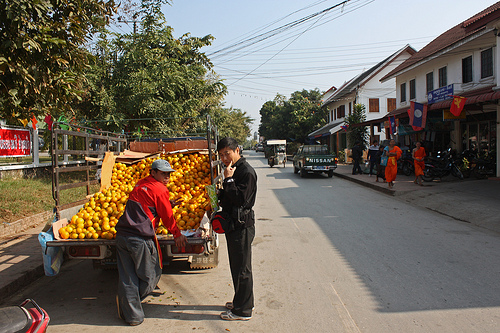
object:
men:
[212, 137, 256, 323]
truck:
[41, 115, 224, 271]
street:
[0, 150, 496, 330]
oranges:
[99, 221, 111, 231]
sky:
[68, 0, 500, 144]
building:
[379, 3, 499, 178]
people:
[366, 139, 382, 177]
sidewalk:
[287, 149, 499, 235]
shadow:
[376, 163, 497, 314]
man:
[114, 159, 187, 326]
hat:
[147, 159, 176, 174]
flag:
[448, 95, 465, 119]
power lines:
[59, 0, 500, 140]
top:
[115, 176, 182, 237]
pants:
[114, 233, 164, 322]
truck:
[294, 145, 339, 178]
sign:
[448, 93, 465, 117]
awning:
[386, 88, 498, 119]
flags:
[405, 100, 428, 131]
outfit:
[210, 156, 257, 319]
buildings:
[296, 0, 498, 177]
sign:
[0, 126, 32, 158]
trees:
[115, 29, 258, 143]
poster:
[425, 82, 453, 102]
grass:
[0, 165, 99, 215]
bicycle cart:
[263, 138, 289, 170]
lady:
[379, 138, 401, 188]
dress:
[383, 146, 402, 183]